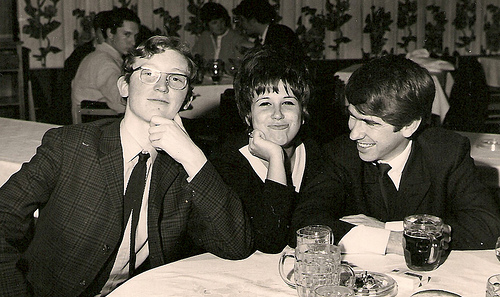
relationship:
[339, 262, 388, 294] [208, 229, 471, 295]
ashtray on table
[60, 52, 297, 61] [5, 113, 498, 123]
people sitting in background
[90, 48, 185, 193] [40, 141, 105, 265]
man in suit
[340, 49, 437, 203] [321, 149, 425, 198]
man in suit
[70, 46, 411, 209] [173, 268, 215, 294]
people at table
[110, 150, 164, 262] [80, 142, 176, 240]
tie on chest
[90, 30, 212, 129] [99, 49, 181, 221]
glasses on man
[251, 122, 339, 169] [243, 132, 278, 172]
chin in hand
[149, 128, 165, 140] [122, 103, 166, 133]
fingers on chin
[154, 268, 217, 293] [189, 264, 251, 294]
tablecloth on table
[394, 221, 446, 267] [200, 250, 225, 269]
glass on table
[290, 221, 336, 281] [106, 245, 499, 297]
glassware on table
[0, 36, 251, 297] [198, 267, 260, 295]
man at table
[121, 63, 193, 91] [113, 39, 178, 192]
glasses on man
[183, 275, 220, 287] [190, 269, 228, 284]
tablecloth on table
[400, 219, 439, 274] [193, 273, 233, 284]
beverage on table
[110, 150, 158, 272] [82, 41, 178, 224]
tie on man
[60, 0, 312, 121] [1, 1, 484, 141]
group talking in background